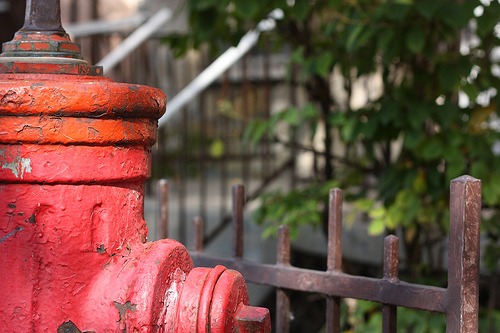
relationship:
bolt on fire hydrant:
[239, 305, 268, 331] [0, 0, 273, 332]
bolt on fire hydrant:
[20, 0, 73, 33] [0, 0, 273, 332]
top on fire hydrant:
[8, 34, 181, 151] [9, 40, 244, 331]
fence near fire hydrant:
[157, 174, 482, 332] [0, 0, 273, 332]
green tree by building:
[165, 2, 490, 227] [80, 2, 382, 227]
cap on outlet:
[211, 271, 269, 329] [116, 241, 255, 323]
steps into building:
[106, 100, 331, 307] [51, 3, 498, 294]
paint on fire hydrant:
[105, 295, 139, 322] [5, 1, 280, 331]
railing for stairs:
[148, 10, 320, 240] [147, 186, 265, 283]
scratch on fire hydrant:
[2, 150, 36, 184] [5, 1, 280, 331]